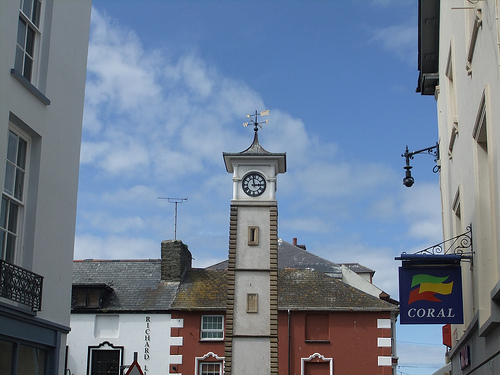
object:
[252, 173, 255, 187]
hands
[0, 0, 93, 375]
wall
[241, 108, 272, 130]
compass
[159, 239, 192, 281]
chimney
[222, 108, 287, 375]
clock tower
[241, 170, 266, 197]
face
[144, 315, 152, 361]
word richard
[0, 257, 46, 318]
balcony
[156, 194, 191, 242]
antenna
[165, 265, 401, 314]
roof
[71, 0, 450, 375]
sky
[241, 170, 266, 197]
clock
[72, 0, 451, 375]
weather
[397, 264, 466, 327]
sign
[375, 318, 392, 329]
brick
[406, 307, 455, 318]
word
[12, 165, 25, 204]
window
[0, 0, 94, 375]
building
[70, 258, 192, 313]
roof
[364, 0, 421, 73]
cloud